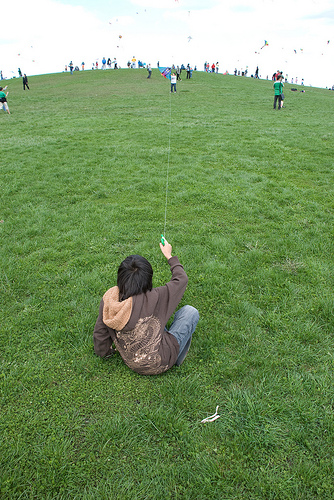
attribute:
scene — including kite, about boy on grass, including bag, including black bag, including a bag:
[4, 1, 331, 496]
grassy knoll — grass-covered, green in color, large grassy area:
[6, 68, 331, 270]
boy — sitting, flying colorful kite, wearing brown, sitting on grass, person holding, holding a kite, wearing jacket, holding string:
[101, 245, 197, 377]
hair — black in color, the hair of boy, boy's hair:
[117, 256, 153, 297]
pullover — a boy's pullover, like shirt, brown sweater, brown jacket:
[96, 264, 183, 373]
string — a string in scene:
[160, 94, 172, 235]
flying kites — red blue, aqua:
[114, 32, 334, 53]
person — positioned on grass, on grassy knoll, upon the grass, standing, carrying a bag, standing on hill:
[271, 78, 285, 110]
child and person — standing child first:
[186, 70, 194, 82]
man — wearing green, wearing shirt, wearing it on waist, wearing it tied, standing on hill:
[0, 87, 14, 114]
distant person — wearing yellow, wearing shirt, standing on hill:
[132, 55, 140, 72]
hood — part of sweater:
[102, 288, 133, 334]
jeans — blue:
[171, 304, 200, 363]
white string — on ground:
[203, 408, 224, 427]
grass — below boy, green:
[27, 401, 163, 490]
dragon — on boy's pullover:
[118, 318, 163, 368]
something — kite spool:
[161, 235, 168, 243]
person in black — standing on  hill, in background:
[23, 75, 32, 89]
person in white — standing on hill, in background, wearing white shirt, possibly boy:
[170, 75, 180, 96]